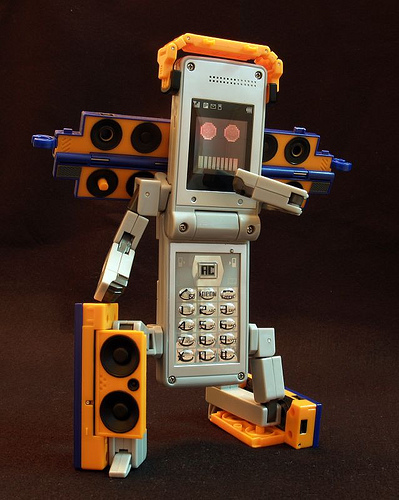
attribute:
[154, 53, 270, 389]
phone — silver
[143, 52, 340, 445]
cellphone — open, silver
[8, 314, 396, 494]
table — dark, textured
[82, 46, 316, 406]
phone — robot